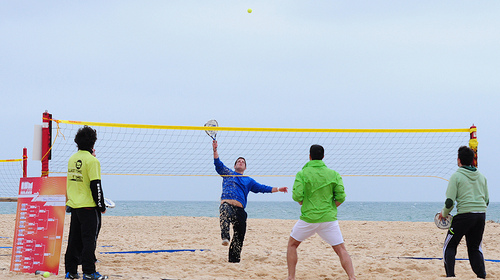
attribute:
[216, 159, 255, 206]
shirt — blue, green, yellow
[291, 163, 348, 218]
jacket — green, lime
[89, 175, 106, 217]
shirt — black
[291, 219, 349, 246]
shorts — white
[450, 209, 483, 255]
pants — black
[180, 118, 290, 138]
net — yellow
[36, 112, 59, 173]
pole — red, white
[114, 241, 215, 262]
boundary marker — blue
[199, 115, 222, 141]
tennis racket — black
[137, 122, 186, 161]
tennis net — yellow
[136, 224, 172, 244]
beach — sandy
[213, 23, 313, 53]
sky — grey, cloudy, blue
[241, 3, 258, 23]
tennis ball — yellow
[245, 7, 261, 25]
ball — yellow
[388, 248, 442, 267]
line — blue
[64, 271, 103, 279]
shoes — blue, black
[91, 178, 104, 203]
sleeve — black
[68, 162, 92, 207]
shirt — yellow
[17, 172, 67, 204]
standings board — red, yellow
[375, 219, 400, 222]
border — blue